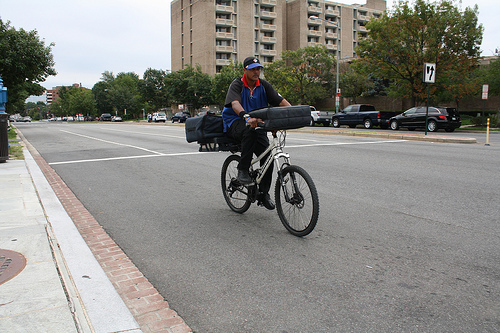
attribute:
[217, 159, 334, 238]
black wheels — white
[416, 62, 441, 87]
sign — white, black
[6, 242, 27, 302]
cover — man hole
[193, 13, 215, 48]
building — red brick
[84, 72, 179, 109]
variety — trees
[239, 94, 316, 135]
pizza carrier — black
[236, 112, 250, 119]
wristband — black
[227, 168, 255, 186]
shoe — black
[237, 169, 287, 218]
shoes — black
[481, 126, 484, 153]
pole — bright, yellow